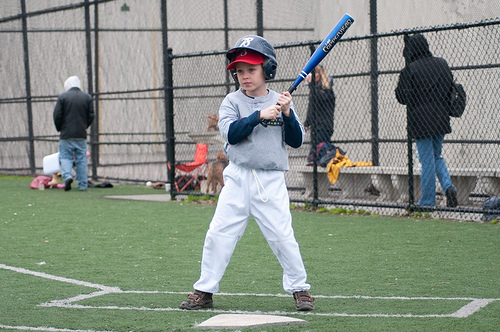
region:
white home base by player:
[217, 302, 252, 330]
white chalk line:
[437, 294, 491, 328]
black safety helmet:
[225, 38, 271, 68]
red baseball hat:
[226, 53, 261, 69]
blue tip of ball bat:
[308, 25, 375, 67]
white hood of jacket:
[50, 49, 106, 111]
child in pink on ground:
[18, 159, 62, 205]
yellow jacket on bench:
[333, 148, 374, 180]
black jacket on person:
[390, 55, 456, 113]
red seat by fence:
[173, 145, 225, 179]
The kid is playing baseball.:
[174, 10, 341, 301]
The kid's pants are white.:
[201, 148, 338, 315]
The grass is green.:
[18, 198, 190, 293]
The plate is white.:
[159, 295, 304, 330]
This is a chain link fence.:
[157, 48, 498, 180]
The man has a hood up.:
[41, 62, 128, 197]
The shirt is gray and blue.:
[221, 83, 323, 181]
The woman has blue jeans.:
[401, 125, 481, 229]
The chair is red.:
[168, 133, 215, 197]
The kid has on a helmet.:
[216, 25, 304, 119]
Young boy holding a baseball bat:
[180, 11, 355, 316]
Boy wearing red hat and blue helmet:
[216, 33, 282, 95]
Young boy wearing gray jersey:
[215, 32, 294, 174]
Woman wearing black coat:
[393, 28, 463, 218]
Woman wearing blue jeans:
[391, 31, 460, 218]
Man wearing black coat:
[49, 75, 95, 192]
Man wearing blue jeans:
[49, 73, 98, 191]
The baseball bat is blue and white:
[297, 12, 354, 77]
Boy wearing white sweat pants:
[184, 35, 301, 313]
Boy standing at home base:
[183, 8, 357, 330]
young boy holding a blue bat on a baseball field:
[175, 13, 356, 312]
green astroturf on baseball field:
[0, 170, 495, 325]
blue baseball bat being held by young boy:
[255, 10, 350, 125]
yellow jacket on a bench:
[321, 145, 372, 185]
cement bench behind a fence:
[282, 162, 497, 212]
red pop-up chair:
[165, 140, 211, 200]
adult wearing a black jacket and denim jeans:
[392, 30, 468, 210]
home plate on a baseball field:
[197, 312, 307, 324]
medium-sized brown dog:
[203, 150, 228, 196]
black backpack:
[449, 75, 469, 117]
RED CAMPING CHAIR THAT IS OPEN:
[167, 139, 213, 200]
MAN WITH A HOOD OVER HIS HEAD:
[52, 74, 97, 194]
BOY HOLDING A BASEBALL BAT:
[178, 14, 360, 314]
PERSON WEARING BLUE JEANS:
[393, 31, 468, 217]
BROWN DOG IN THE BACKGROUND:
[202, 149, 231, 200]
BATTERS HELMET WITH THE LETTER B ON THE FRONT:
[227, 34, 277, 81]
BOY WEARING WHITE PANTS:
[176, 14, 356, 314]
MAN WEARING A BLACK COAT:
[49, 74, 100, 192]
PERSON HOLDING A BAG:
[391, 31, 468, 216]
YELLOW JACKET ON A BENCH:
[320, 147, 375, 184]